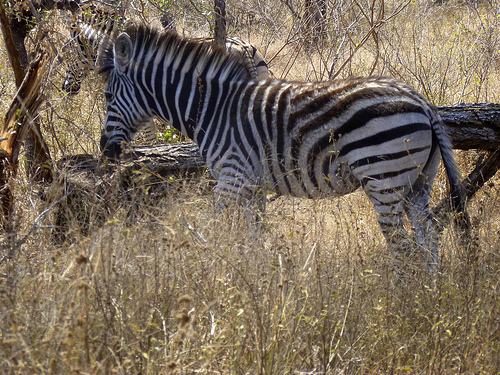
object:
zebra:
[90, 18, 467, 291]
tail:
[428, 118, 481, 258]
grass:
[70, 233, 474, 375]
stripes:
[216, 88, 310, 152]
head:
[90, 23, 155, 160]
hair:
[296, 80, 345, 109]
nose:
[98, 137, 119, 155]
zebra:
[59, 8, 274, 99]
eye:
[103, 87, 116, 103]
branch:
[10, 41, 59, 192]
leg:
[368, 190, 417, 265]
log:
[62, 97, 498, 198]